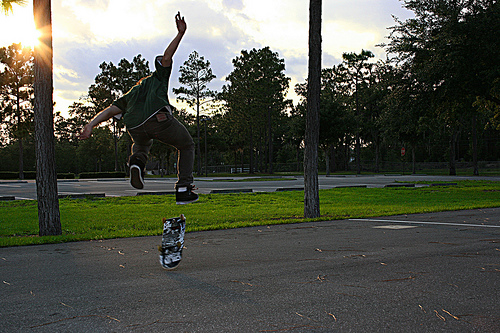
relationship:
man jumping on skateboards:
[87, 42, 243, 178] [150, 206, 198, 278]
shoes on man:
[122, 156, 202, 204] [73, 6, 217, 201]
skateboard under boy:
[151, 203, 197, 279] [77, 11, 201, 205]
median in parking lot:
[1, 177, 498, 246] [0, 175, 497, 332]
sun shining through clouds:
[18, 20, 58, 54] [44, 1, 194, 72]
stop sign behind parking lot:
[398, 144, 407, 176] [2, 172, 483, 198]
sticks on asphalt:
[441, 303, 466, 324] [375, 238, 489, 316]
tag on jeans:
[154, 101, 175, 135] [127, 112, 195, 188]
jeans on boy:
[127, 112, 195, 188] [59, 8, 232, 209]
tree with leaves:
[215, 53, 295, 151] [216, 40, 310, 177]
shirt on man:
[110, 52, 175, 132] [74, 9, 199, 201]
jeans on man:
[121, 111, 198, 191] [110, 56, 218, 194]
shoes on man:
[109, 150, 191, 207] [97, 56, 223, 192]